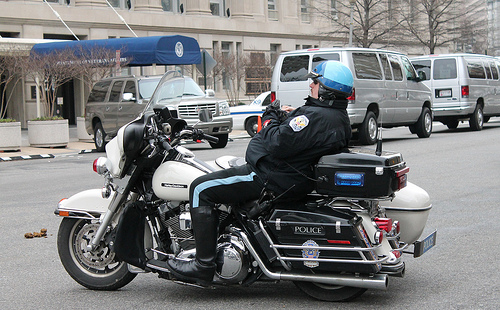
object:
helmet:
[297, 60, 352, 97]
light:
[460, 86, 467, 97]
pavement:
[0, 128, 252, 161]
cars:
[82, 73, 233, 150]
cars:
[221, 90, 279, 140]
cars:
[268, 47, 434, 145]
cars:
[408, 52, 500, 131]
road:
[0, 117, 499, 310]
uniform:
[187, 96, 353, 261]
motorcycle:
[52, 70, 436, 304]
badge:
[288, 114, 310, 132]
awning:
[26, 35, 203, 69]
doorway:
[46, 71, 80, 128]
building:
[0, 0, 499, 130]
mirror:
[413, 69, 425, 83]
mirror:
[119, 91, 136, 101]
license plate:
[413, 229, 437, 258]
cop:
[163, 60, 358, 289]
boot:
[163, 204, 222, 288]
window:
[137, 76, 204, 101]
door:
[46, 75, 75, 125]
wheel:
[56, 205, 142, 291]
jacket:
[244, 97, 350, 194]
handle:
[158, 138, 178, 159]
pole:
[40, 0, 79, 41]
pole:
[104, 0, 139, 38]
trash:
[23, 226, 49, 240]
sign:
[296, 238, 320, 269]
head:
[304, 58, 356, 103]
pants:
[186, 163, 261, 210]